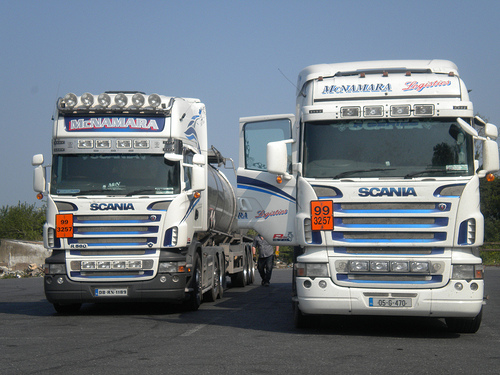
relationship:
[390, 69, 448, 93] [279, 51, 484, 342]
writing on truck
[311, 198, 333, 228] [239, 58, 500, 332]
sign on truck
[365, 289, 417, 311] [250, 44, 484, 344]
tag on truck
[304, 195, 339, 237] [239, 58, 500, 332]
sign on truck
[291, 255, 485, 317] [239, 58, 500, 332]
bumper on truck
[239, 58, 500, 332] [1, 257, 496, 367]
truck on road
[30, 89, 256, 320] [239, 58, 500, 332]
truck parked next to truck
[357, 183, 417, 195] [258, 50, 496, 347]
lettering on front of truck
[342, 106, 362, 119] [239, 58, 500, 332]
light in truck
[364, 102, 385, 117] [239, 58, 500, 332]
light in truck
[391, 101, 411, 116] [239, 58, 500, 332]
light in truck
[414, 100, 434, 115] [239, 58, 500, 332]
light in truck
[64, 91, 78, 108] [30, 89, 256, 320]
light in truck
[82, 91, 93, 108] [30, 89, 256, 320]
light in truck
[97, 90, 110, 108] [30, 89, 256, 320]
light in truck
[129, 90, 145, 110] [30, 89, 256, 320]
light in truck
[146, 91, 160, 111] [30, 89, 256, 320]
light in truck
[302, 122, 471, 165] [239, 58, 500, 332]
window of truck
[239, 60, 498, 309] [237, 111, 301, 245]
truck with door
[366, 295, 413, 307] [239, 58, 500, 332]
license plate on a truck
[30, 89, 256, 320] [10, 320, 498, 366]
truck on road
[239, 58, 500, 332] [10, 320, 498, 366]
truck on road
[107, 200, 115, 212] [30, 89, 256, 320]
blue letter on truck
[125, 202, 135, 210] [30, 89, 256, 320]
letter on truck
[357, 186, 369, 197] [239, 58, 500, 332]
blue letter on truck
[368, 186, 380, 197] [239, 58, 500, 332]
blue letter on truck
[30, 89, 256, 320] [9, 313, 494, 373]
truck on road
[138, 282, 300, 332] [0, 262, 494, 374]
shadow on ground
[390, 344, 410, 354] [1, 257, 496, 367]
spot on road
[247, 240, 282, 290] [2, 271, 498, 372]
man on ground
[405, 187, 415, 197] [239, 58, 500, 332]
blue letter on truck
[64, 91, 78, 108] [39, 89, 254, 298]
light on truck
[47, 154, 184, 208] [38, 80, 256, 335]
window on truck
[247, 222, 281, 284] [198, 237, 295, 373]
man on road